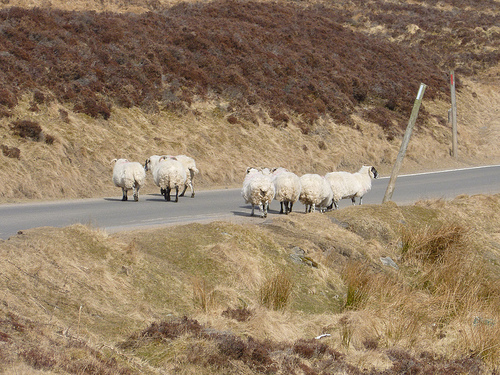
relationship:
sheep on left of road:
[105, 148, 204, 203] [100, 200, 231, 220]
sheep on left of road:
[152, 155, 188, 203] [47, 204, 134, 224]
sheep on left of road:
[241, 164, 273, 217] [383, 173, 481, 193]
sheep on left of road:
[241, 164, 273, 217] [13, 152, 483, 259]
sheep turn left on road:
[225, 163, 420, 225] [99, 201, 235, 219]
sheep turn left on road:
[143, 154, 199, 198] [14, 197, 236, 232]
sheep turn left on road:
[143, 154, 199, 198] [0, 166, 500, 239]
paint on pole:
[445, 72, 455, 87] [381, 69, 452, 171]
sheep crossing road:
[143, 154, 199, 198] [50, 206, 226, 228]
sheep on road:
[86, 122, 405, 243] [76, 199, 234, 222]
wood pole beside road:
[382, 78, 431, 206] [2, 193, 240, 233]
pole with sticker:
[443, 65, 462, 167] [447, 74, 456, 89]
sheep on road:
[108, 155, 147, 202] [0, 166, 500, 239]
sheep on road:
[325, 162, 378, 207] [0, 166, 500, 239]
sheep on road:
[298, 173, 334, 213] [0, 166, 500, 239]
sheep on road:
[241, 164, 273, 217] [0, 166, 500, 239]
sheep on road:
[273, 168, 303, 210] [0, 166, 500, 239]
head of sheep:
[142, 148, 157, 168] [142, 153, 199, 197]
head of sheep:
[359, 159, 381, 184] [323, 167, 380, 200]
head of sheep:
[243, 166, 257, 173] [246, 167, 272, 207]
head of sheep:
[272, 165, 285, 173] [270, 162, 299, 209]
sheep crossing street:
[323, 166, 379, 210] [6, 131, 498, 237]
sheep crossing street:
[298, 173, 334, 213] [6, 131, 498, 237]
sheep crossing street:
[273, 168, 303, 210] [6, 131, 498, 237]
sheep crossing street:
[241, 164, 273, 217] [6, 131, 498, 237]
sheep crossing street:
[108, 157, 147, 201] [6, 131, 498, 237]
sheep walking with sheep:
[152, 155, 188, 203] [108, 155, 147, 202]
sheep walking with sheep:
[108, 155, 147, 202] [141, 156, 198, 203]